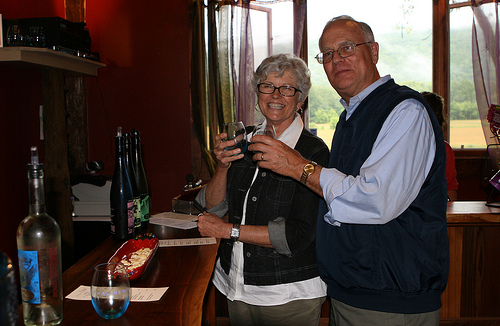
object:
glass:
[89, 262, 132, 324]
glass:
[251, 123, 277, 153]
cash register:
[71, 161, 114, 222]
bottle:
[15, 146, 63, 326]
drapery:
[468, 0, 500, 164]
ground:
[432, 316, 500, 326]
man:
[247, 14, 449, 325]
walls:
[80, 0, 201, 213]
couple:
[193, 15, 449, 326]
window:
[187, 0, 500, 163]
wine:
[225, 139, 247, 157]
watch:
[226, 215, 242, 245]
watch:
[300, 161, 319, 185]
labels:
[127, 201, 135, 235]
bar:
[20, 207, 220, 326]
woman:
[195, 54, 332, 326]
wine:
[13, 144, 66, 322]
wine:
[109, 126, 135, 242]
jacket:
[313, 78, 448, 313]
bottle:
[108, 126, 134, 243]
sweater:
[213, 127, 333, 286]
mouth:
[265, 101, 287, 111]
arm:
[225, 181, 322, 258]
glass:
[222, 120, 248, 157]